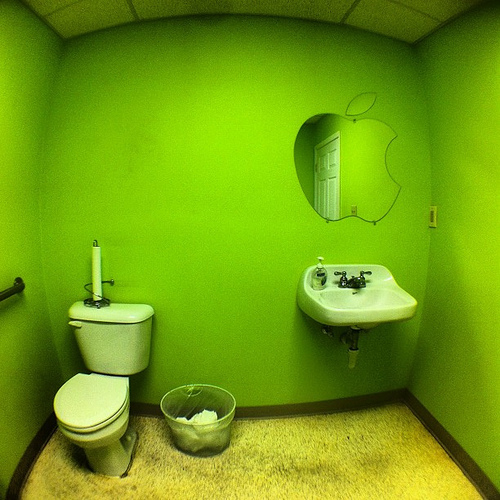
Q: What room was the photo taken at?
A: It was taken at the bathroom.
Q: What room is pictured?
A: It is a bathroom.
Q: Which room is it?
A: It is a bathroom.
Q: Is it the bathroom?
A: Yes, it is the bathroom.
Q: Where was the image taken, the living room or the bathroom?
A: It was taken at the bathroom.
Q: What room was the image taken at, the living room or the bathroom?
A: It was taken at the bathroom.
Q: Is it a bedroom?
A: No, it is a bathroom.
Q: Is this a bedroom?
A: No, it is a bathroom.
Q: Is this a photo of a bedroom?
A: No, the picture is showing a bathroom.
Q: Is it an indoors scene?
A: Yes, it is indoors.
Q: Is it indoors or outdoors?
A: It is indoors.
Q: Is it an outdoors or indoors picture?
A: It is indoors.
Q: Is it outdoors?
A: No, it is indoors.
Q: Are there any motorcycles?
A: No, there are no motorcycles.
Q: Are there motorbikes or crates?
A: No, there are no motorbikes or crates.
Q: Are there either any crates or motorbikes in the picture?
A: No, there are no motorbikes or crates.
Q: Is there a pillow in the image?
A: No, there are no pillows.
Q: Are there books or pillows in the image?
A: No, there are no pillows or books.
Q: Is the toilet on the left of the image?
A: Yes, the toilet is on the left of the image.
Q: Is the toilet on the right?
A: No, the toilet is on the left of the image.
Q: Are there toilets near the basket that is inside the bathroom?
A: Yes, there is a toilet near the basket.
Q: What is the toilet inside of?
A: The toilet is inside the bathroom.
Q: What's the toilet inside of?
A: The toilet is inside the bathroom.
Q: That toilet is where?
A: The toilet is in the bathroom.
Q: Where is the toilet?
A: The toilet is in the bathroom.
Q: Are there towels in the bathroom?
A: No, there is a toilet in the bathroom.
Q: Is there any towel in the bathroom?
A: No, there is a toilet in the bathroom.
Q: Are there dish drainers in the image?
A: No, there are no dish drainers.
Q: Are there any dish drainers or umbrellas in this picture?
A: No, there are no dish drainers or umbrellas.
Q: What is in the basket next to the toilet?
A: The trash is in the basket.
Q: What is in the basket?
A: The trash is in the basket.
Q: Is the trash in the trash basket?
A: Yes, the trash is in the basket.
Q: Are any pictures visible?
A: No, there are no pictures.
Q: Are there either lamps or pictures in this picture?
A: No, there are no pictures or lamps.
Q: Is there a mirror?
A: Yes, there is a mirror.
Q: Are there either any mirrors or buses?
A: Yes, there is a mirror.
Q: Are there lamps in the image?
A: No, there are no lamps.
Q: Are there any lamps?
A: No, there are no lamps.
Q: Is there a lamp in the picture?
A: No, there are no lamps.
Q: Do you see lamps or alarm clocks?
A: No, there are no lamps or alarm clocks.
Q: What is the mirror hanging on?
A: The mirror is hanging on the wall.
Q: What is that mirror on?
A: The mirror is on the wall.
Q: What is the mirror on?
A: The mirror is on the wall.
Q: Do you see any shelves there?
A: No, there are no shelves.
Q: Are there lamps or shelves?
A: No, there are no shelves or lamps.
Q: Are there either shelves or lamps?
A: No, there are no shelves or lamps.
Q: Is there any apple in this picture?
A: Yes, there is an apple.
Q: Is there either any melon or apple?
A: Yes, there is an apple.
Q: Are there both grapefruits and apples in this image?
A: No, there is an apple but no grapefruits.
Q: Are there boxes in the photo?
A: No, there are no boxes.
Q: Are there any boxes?
A: No, there are no boxes.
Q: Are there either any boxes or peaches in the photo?
A: No, there are no boxes or peaches.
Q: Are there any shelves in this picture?
A: No, there are no shelves.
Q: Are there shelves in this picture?
A: No, there are no shelves.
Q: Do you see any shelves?
A: No, there are no shelves.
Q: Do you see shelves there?
A: No, there are no shelves.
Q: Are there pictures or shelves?
A: No, there are no shelves or pictures.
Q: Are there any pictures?
A: No, there are no pictures.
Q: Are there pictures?
A: No, there are no pictures.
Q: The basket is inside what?
A: The basket is inside the bathroom.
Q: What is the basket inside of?
A: The basket is inside the bathroom.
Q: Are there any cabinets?
A: No, there are no cabinets.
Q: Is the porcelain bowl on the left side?
A: Yes, the bowl is on the left of the image.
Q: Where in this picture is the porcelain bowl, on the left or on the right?
A: The bowl is on the left of the image.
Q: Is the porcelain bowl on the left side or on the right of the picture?
A: The bowl is on the left of the image.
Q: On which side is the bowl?
A: The bowl is on the left of the image.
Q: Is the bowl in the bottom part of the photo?
A: Yes, the bowl is in the bottom of the image.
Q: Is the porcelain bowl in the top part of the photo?
A: No, the bowl is in the bottom of the image.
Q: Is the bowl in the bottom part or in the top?
A: The bowl is in the bottom of the image.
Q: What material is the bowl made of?
A: The bowl is made of porcelain.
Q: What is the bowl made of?
A: The bowl is made of porcelain.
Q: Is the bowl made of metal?
A: No, the bowl is made of porcelain.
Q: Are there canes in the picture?
A: No, there are no canes.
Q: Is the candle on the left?
A: Yes, the candle is on the left of the image.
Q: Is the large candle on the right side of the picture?
A: No, the candle is on the left of the image.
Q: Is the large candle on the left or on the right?
A: The candle is on the left of the image.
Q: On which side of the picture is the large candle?
A: The candle is on the left of the image.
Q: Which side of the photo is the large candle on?
A: The candle is on the left of the image.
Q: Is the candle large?
A: Yes, the candle is large.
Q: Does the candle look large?
A: Yes, the candle is large.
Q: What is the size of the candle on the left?
A: The candle is large.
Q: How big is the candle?
A: The candle is large.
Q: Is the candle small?
A: No, the candle is large.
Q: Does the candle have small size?
A: No, the candle is large.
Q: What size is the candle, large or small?
A: The candle is large.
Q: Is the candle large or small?
A: The candle is large.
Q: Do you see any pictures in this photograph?
A: No, there are no pictures.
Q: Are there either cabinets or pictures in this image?
A: No, there are no pictures or cabinets.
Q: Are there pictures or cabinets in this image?
A: No, there are no pictures or cabinets.